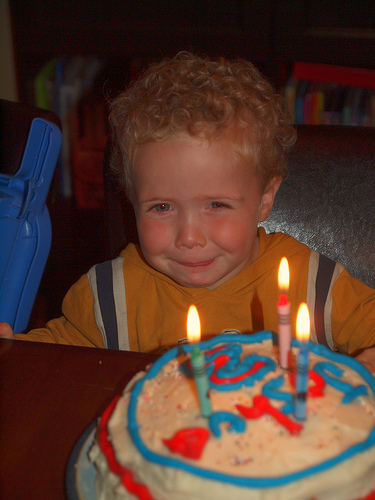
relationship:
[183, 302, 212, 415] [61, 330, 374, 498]
candle on birthday cake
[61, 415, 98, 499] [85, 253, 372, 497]
platter under cake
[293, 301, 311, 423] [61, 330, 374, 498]
candle on top of birthday cake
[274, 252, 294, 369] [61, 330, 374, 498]
candle on top of birthday cake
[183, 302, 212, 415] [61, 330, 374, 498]
candle on top of birthday cake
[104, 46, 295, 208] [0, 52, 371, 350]
curly hair on boy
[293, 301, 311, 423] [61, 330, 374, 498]
candle on birthday cake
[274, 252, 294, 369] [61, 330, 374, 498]
candle on birthday cake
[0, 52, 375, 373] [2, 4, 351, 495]
boy crying at party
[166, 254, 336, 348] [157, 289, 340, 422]
flames on candles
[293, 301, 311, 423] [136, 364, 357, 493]
candle on cake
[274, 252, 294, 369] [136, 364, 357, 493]
candle on cake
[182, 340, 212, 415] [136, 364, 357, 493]
candle on cake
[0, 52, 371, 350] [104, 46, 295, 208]
boy with curly hair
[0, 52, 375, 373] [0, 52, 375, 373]
boy with boy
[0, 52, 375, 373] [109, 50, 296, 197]
boy with curly hair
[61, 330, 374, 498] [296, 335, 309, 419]
birthday cake with candle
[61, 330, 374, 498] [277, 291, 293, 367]
birthday cake with candle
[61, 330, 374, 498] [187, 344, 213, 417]
birthday cake with candle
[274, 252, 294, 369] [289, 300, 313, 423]
candle shaped like candle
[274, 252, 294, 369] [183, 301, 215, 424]
candle shaped like candle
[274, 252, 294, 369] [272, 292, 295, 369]
candle shaped like red crayon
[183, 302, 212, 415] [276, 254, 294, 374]
candle lit on candles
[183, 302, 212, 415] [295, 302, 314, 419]
candle lit on candles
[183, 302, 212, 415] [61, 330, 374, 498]
candle lit on birthday cake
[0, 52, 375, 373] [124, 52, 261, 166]
boy with hair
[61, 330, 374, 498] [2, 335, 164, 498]
birthday cake on a table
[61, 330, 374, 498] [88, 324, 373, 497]
birthday cake with frosting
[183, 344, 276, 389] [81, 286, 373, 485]
number 2 on cake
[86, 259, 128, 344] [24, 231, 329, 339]
stripe on a shirt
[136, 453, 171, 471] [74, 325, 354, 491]
blue icing on a cake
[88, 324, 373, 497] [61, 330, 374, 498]
frosting on birthday cake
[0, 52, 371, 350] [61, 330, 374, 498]
boy in front of birthday cake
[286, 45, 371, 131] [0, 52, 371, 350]
books behind boy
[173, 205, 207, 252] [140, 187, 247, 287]
nose on face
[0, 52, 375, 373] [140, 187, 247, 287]
boy has face